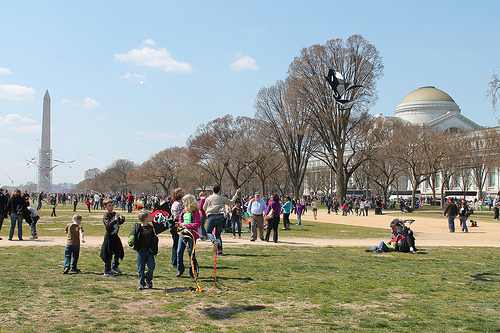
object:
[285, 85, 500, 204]
building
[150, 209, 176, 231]
kite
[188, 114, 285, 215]
trees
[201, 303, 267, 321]
shadow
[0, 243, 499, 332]
grass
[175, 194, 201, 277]
girl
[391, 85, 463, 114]
dome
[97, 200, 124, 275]
kid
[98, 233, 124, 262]
jacket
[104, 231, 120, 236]
waist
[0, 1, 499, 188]
sky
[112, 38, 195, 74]
clouds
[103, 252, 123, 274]
jeans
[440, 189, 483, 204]
bus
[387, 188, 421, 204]
bus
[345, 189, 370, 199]
bus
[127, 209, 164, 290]
kid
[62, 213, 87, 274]
kid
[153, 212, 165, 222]
skull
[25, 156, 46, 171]
kite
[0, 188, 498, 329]
park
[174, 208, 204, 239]
jacket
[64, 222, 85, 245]
shirt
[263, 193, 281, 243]
lady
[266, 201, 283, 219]
shirt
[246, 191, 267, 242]
man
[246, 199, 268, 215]
shirt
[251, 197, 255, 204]
bag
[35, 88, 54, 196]
monument